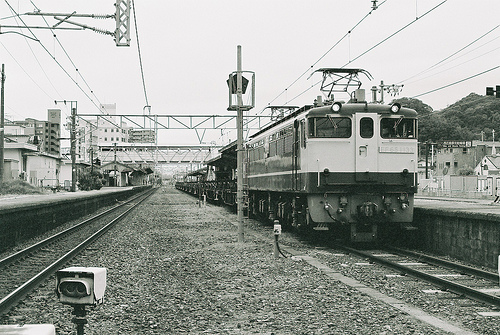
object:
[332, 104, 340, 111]
headlight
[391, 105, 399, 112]
headlight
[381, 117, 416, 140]
window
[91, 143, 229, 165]
bridge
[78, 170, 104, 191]
bush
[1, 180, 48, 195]
bush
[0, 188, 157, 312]
tracks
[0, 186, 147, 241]
wall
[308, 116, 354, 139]
window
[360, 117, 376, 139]
window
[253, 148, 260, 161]
window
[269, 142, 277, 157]
window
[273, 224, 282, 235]
electric outlet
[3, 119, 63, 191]
building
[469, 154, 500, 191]
house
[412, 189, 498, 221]
road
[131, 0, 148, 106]
wire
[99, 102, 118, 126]
skyscrapers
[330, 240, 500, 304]
rail guage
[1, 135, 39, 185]
houses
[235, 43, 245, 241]
pole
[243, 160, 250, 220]
staircase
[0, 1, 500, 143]
sky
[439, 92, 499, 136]
hills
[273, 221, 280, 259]
pole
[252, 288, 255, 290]
gravel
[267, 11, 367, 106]
wire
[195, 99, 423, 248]
cable car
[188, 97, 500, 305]
train/tracks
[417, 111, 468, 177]
trees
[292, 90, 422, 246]
locomotive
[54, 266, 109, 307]
camera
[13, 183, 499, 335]
ground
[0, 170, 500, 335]
railway station